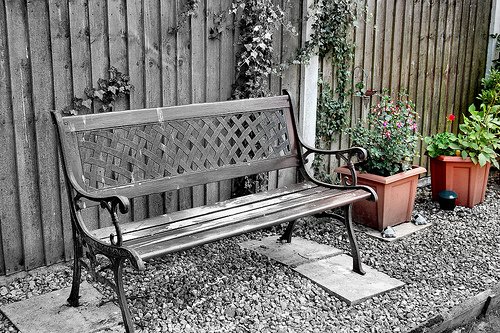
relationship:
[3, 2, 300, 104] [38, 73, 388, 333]
fence behind bench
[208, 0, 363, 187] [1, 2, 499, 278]
plant growing fence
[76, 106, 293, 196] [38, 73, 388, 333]
lattice of bench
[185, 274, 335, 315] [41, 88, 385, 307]
gravel under bench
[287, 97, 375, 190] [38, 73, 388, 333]
arm rail on bench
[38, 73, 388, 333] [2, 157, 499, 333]
bench on ground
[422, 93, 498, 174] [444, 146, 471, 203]
plant in pot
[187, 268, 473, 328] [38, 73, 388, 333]
rocks near bench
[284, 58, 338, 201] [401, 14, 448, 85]
post in fence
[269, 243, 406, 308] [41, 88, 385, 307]
cement under bench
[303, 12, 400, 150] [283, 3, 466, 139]
greenery on fence